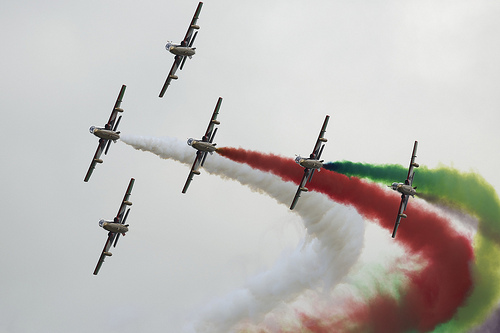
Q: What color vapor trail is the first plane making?
A: White.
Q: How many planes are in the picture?
A: 6.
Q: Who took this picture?
A: A spectator.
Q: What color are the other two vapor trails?
A: Red & Green.